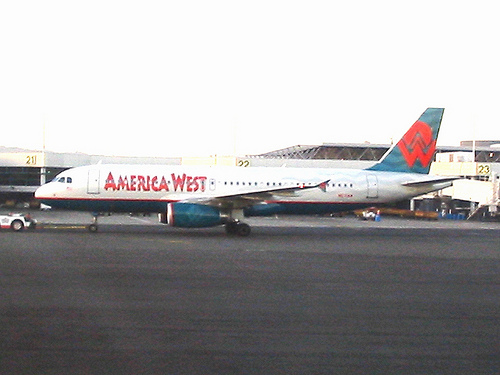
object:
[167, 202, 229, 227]
engine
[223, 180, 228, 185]
windows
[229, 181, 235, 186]
windows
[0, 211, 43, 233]
car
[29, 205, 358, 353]
runway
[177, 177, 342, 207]
wing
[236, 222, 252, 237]
tire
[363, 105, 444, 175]
tail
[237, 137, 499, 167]
roof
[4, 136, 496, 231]
terminal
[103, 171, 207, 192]
brand name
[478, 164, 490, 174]
23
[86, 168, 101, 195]
door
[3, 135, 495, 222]
airport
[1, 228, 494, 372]
tarmac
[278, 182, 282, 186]
windows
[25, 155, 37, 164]
21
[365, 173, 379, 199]
back door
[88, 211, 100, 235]
landing gear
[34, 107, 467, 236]
airliner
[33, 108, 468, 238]
plane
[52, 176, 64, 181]
windshield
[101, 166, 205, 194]
writing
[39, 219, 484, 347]
plane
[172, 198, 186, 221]
part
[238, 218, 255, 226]
edge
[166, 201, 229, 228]
booster jet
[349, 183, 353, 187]
window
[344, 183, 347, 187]
window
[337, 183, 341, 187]
window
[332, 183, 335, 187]
window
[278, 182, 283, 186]
window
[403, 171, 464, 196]
fin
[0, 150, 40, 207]
building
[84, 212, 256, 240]
equipment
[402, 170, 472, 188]
wing